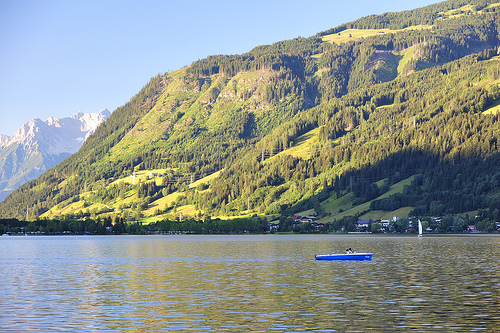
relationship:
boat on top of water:
[315, 252, 374, 262] [2, 261, 499, 332]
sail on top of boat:
[416, 216, 425, 232] [415, 233, 424, 239]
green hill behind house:
[229, 47, 499, 194] [355, 217, 373, 228]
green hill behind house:
[229, 47, 499, 194] [378, 219, 392, 230]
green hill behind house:
[229, 47, 499, 194] [297, 213, 318, 221]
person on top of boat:
[347, 245, 355, 254] [315, 252, 374, 262]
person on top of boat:
[342, 247, 349, 255] [311, 253, 375, 261]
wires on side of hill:
[343, 126, 407, 145] [229, 47, 499, 194]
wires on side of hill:
[266, 144, 350, 157] [229, 47, 499, 194]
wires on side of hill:
[163, 170, 217, 190] [229, 47, 499, 194]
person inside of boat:
[347, 245, 355, 254] [315, 252, 374, 262]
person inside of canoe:
[342, 247, 349, 255] [311, 253, 375, 261]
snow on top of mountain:
[4, 109, 88, 139] [2, 107, 113, 192]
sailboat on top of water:
[414, 217, 425, 237] [2, 261, 499, 332]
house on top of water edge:
[355, 217, 373, 228] [238, 232, 499, 248]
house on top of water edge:
[378, 219, 392, 230] [238, 232, 499, 248]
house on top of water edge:
[297, 213, 318, 221] [238, 232, 499, 248]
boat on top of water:
[415, 233, 424, 239] [2, 261, 499, 332]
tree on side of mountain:
[340, 105, 360, 131] [229, 47, 499, 194]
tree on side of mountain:
[323, 120, 337, 140] [229, 47, 499, 194]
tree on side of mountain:
[278, 130, 289, 150] [229, 47, 499, 194]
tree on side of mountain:
[317, 110, 329, 128] [229, 47, 499, 194]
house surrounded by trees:
[297, 213, 318, 221] [277, 214, 314, 234]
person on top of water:
[347, 245, 355, 254] [2, 261, 499, 332]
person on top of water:
[342, 247, 349, 255] [2, 261, 499, 332]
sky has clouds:
[2, 1, 147, 80] [26, 26, 82, 59]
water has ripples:
[2, 261, 499, 332] [134, 290, 253, 327]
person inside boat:
[347, 245, 355, 254] [311, 253, 375, 261]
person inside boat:
[342, 247, 349, 255] [311, 253, 375, 261]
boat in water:
[415, 233, 424, 239] [2, 261, 499, 332]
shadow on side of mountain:
[277, 144, 499, 208] [229, 47, 499, 194]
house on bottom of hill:
[355, 217, 373, 228] [229, 47, 499, 194]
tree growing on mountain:
[278, 130, 289, 150] [229, 47, 499, 194]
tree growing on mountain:
[317, 110, 329, 128] [229, 47, 499, 194]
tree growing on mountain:
[340, 105, 360, 131] [229, 47, 499, 194]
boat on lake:
[315, 252, 374, 262] [2, 234, 499, 332]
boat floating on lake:
[311, 253, 375, 261] [2, 234, 499, 332]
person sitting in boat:
[347, 245, 355, 254] [311, 253, 375, 261]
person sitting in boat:
[342, 247, 349, 255] [311, 253, 375, 261]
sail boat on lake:
[414, 217, 425, 237] [2, 234, 499, 332]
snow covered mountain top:
[4, 109, 88, 139] [1, 107, 112, 160]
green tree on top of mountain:
[355, 21, 363, 32] [229, 47, 499, 194]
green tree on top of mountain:
[374, 21, 382, 31] [229, 47, 499, 194]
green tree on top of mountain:
[388, 23, 396, 33] [229, 47, 499, 194]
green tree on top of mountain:
[355, 22, 363, 31] [229, 47, 499, 194]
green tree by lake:
[86, 219, 97, 234] [2, 234, 499, 332]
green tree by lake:
[23, 222, 37, 232] [2, 234, 499, 332]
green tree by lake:
[69, 220, 78, 234] [2, 234, 499, 332]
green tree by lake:
[111, 220, 122, 234] [2, 234, 499, 332]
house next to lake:
[355, 217, 373, 228] [2, 234, 499, 332]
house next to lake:
[378, 219, 392, 230] [2, 234, 499, 332]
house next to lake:
[297, 213, 318, 221] [2, 234, 499, 332]